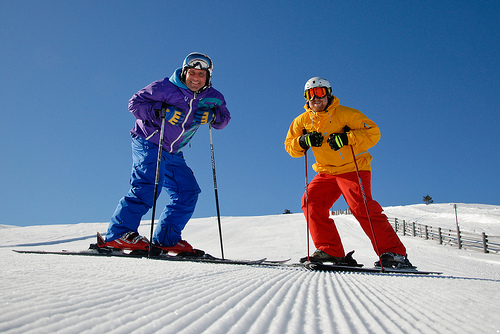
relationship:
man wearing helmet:
[281, 74, 418, 267] [303, 75, 331, 92]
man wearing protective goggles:
[281, 74, 418, 267] [303, 84, 332, 102]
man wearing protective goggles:
[109, 40, 239, 256] [179, 53, 217, 72]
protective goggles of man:
[303, 84, 332, 102] [281, 74, 418, 267]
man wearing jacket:
[281, 74, 418, 267] [278, 102, 382, 174]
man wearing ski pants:
[281, 74, 418, 267] [297, 166, 397, 259]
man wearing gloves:
[281, 74, 418, 267] [300, 128, 347, 153]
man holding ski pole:
[281, 74, 418, 267] [341, 143, 397, 276]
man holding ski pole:
[281, 74, 418, 267] [295, 131, 324, 266]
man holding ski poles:
[109, 40, 239, 256] [144, 102, 234, 258]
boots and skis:
[304, 239, 409, 267] [293, 256, 447, 279]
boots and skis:
[102, 227, 199, 250] [16, 239, 294, 268]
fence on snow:
[386, 202, 500, 261] [3, 187, 492, 332]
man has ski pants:
[281, 74, 418, 267] [297, 166, 397, 259]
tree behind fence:
[422, 192, 435, 208] [386, 202, 500, 261]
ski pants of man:
[116, 136, 209, 239] [109, 40, 239, 256]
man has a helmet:
[281, 74, 418, 267] [303, 75, 331, 92]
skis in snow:
[293, 256, 447, 279] [3, 187, 492, 332]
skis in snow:
[16, 239, 294, 268] [3, 187, 492, 332]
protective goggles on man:
[303, 84, 332, 102] [281, 74, 418, 267]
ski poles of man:
[144, 102, 234, 258] [109, 40, 239, 256]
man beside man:
[281, 74, 418, 267] [109, 40, 239, 256]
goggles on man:
[179, 53, 217, 72] [109, 40, 239, 256]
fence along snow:
[386, 202, 500, 261] [3, 187, 492, 332]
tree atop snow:
[422, 192, 435, 208] [3, 187, 492, 332]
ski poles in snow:
[144, 102, 234, 258] [3, 187, 492, 332]